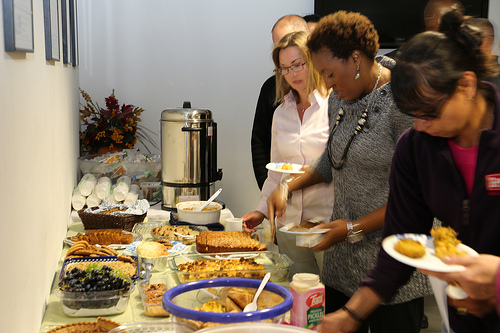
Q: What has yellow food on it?
A: The white dish.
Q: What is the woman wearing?
A: A necklace.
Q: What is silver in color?
A: Coffee dispenser.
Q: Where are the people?
A: In a room.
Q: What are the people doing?
A: Getting food?.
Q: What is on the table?
A: Some food.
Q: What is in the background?
A: A wall.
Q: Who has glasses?
A: A woman.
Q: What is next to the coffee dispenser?
A: Flowers.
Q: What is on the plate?
A: Food.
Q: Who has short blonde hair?
A: Black woman.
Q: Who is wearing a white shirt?
A: The woman.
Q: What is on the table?
A: Food.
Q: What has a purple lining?
A: The bowl.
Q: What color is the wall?
A: White.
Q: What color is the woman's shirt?
A: Grey.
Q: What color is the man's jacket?
A: Black.